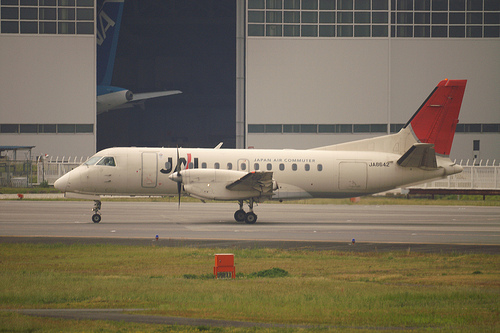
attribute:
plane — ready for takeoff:
[50, 78, 469, 227]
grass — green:
[321, 251, 429, 316]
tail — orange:
[404, 77, 469, 159]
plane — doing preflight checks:
[37, 58, 472, 273]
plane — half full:
[20, 81, 495, 228]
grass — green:
[287, 251, 462, 310]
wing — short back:
[174, 160, 361, 246]